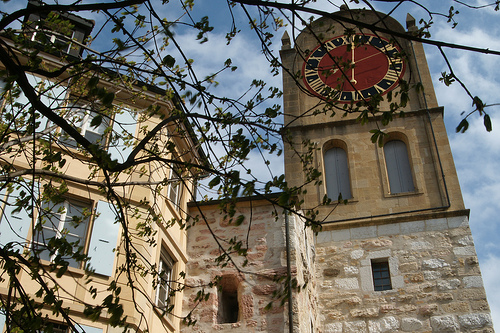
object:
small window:
[369, 257, 392, 291]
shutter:
[85, 201, 123, 277]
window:
[370, 257, 393, 291]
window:
[30, 189, 95, 269]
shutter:
[0, 172, 39, 254]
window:
[215, 274, 239, 325]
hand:
[350, 36, 357, 84]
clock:
[301, 33, 406, 103]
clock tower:
[280, 5, 495, 333]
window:
[31, 16, 76, 54]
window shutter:
[86, 201, 122, 277]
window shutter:
[0, 172, 41, 254]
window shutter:
[107, 106, 138, 163]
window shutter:
[1, 71, 66, 139]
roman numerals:
[309, 77, 327, 93]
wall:
[278, 9, 466, 225]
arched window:
[382, 131, 414, 194]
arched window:
[322, 138, 353, 201]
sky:
[0, 0, 499, 331]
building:
[0, 0, 499, 333]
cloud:
[0, 0, 500, 331]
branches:
[0, 0, 500, 333]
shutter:
[2, 71, 67, 142]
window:
[56, 93, 112, 154]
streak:
[81, 0, 277, 58]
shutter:
[106, 107, 139, 164]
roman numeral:
[351, 90, 365, 100]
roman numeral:
[383, 69, 401, 82]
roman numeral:
[323, 41, 337, 52]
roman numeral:
[381, 43, 395, 51]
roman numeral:
[305, 68, 318, 78]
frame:
[372, 261, 392, 291]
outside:
[2, 0, 500, 333]